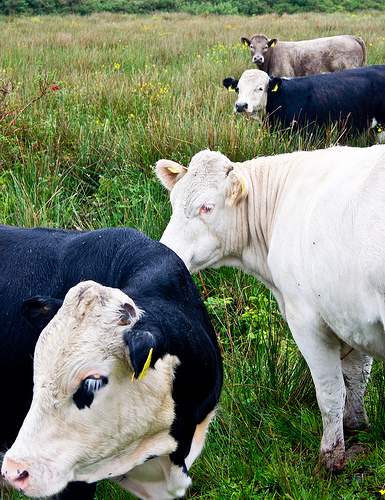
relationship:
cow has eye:
[240, 30, 369, 69] [244, 37, 271, 55]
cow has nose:
[240, 30, 369, 69] [252, 52, 266, 63]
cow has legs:
[240, 30, 369, 69] [287, 319, 374, 465]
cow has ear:
[240, 30, 369, 69] [231, 28, 281, 44]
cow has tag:
[240, 30, 369, 69] [136, 345, 161, 380]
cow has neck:
[240, 30, 369, 69] [162, 144, 288, 288]